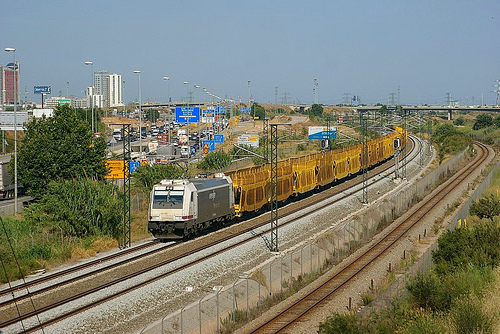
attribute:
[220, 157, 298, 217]
train car — yellow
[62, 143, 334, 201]
fence — side 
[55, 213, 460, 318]
tracks — train 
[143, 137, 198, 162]
traffic — lots 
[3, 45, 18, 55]
street light — tall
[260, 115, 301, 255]
tower — metal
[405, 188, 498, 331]
bush — Leafy green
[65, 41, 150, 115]
building — Tall white 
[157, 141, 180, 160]
truck — diesel 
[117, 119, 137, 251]
tower — metal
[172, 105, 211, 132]
sign — blue traffic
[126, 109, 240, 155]
road — over 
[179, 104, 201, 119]
sign — blue 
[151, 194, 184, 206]
window — train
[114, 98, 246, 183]
road — over 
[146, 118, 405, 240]
train — yellow, beside 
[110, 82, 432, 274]
train — white 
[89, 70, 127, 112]
building — white, background.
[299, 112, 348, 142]
billboard — white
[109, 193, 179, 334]
windows — many 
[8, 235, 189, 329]
tracks — train 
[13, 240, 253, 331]
track — side .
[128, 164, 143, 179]
lettering — white 